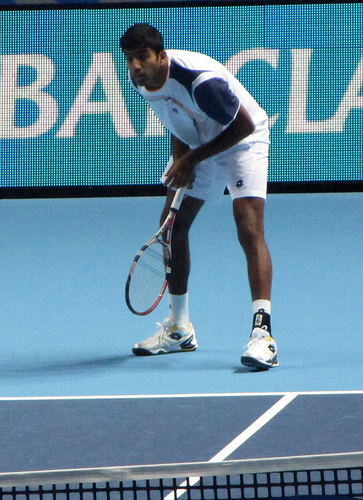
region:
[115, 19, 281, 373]
man playing tennis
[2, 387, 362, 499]
white lines on blue court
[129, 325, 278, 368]
white and black shoes of tennis player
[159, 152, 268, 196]
white shorts of tennis player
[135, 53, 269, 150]
white shirt with navy sleeves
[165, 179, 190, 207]
white handle of tennis racket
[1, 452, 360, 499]
black netting with white tape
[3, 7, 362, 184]
digital advertisement board behind tennis player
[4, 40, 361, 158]
white lettering on blue background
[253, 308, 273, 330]
black ankle wrap of tennis player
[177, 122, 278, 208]
WHITE SHORTS ON TENNIS PLAYER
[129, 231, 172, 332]
TENNIS RACKET IN HAND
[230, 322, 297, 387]
WHITE SNEAKER ON TENNIS PLAYER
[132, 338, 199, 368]
WHITE SNEAKER ON TENNIS PLAYER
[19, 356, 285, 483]
BLUE SURFACE OF TENNIS COURT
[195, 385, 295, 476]
WHITE LINE ON TENNIS COURT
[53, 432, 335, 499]
NET CROSSING ON COURT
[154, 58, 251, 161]
WHITE AND BLUE SHIRT ON PLAYER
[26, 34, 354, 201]
LIT SIGN BEHIND PLAYER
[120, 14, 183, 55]
DARK HAIR OF TENNIS PLAYER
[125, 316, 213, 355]
right foot on man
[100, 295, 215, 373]
right shoe on man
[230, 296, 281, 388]
left foot on man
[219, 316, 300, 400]
left shoe on man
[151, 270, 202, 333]
white sock on man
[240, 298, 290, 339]
white sock on man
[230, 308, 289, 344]
ankle brace on man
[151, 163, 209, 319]
man with tennis racket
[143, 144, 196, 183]
left hand on man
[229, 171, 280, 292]
left leg on man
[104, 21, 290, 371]
tennis player on tennis court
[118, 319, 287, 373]
black and white sneakers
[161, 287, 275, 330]
pair of white cotton socks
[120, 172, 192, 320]
tennis racket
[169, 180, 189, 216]
white handle on tennis racket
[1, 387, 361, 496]
white lines on tennis court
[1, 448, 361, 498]
black and white tennis net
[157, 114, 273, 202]
pair of white shorts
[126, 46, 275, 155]
short sleeve white shirt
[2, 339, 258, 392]
shadow of man on tennis court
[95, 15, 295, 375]
man standing on tennis court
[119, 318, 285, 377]
pair of black and white sneakers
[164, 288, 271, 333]
pair of cotton white socks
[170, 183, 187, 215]
white handle of tennis racket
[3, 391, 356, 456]
white lines drawn on tennis court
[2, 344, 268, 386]
black shadow of tennis player on tennis court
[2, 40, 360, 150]
advertising sign in background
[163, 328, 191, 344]
black logo on side of sneaker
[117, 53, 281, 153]
white and blue short sleeve shirt